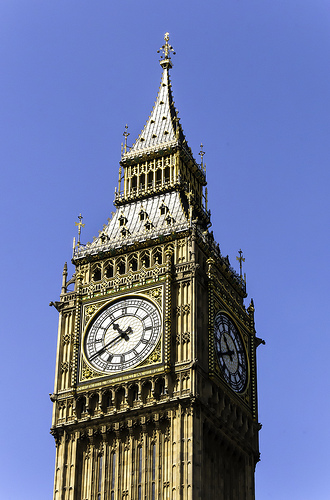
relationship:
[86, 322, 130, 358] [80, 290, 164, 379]
hands on clock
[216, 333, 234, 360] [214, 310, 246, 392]
hands on clock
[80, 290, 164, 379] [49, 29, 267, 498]
clock on building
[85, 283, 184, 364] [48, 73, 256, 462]
clock on tower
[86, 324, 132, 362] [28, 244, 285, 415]
hands on clock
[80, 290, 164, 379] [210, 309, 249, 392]
clock on a clock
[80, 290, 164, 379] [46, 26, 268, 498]
clock on a tower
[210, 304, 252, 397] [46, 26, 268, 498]
clock on a tower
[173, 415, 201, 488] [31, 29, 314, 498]
edge of a tower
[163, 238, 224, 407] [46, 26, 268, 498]
edge of a tower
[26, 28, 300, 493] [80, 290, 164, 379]
close shot of clock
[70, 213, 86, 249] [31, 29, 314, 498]
ornamental pole on a tower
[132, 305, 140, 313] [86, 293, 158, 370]
roman numeral on a clock